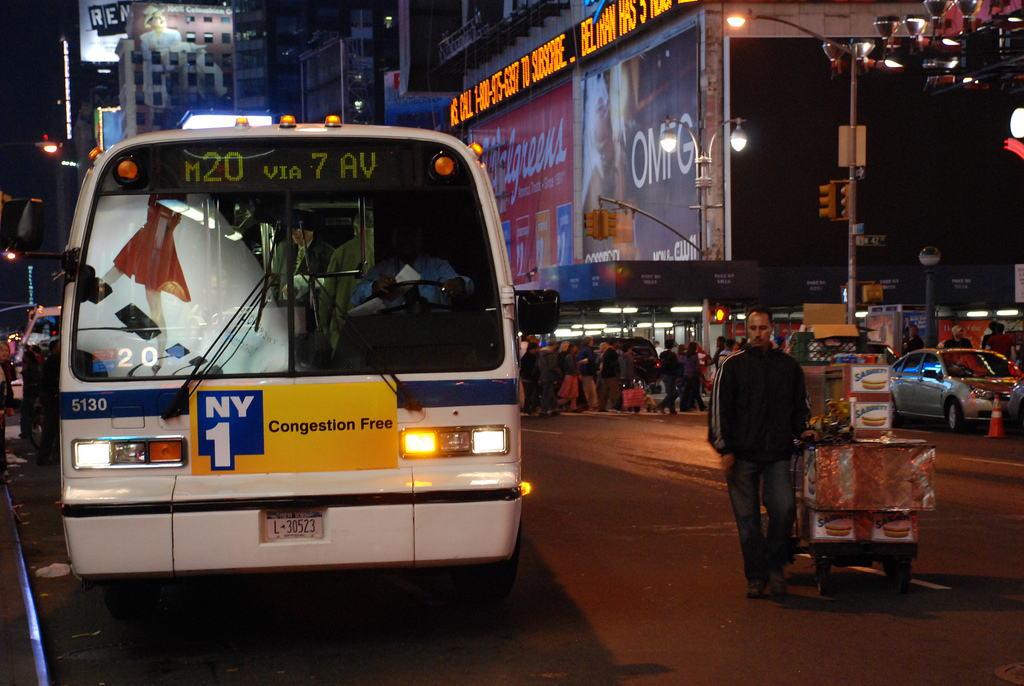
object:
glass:
[71, 138, 504, 383]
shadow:
[0, 529, 676, 684]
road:
[0, 411, 1024, 678]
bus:
[0, 115, 560, 612]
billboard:
[451, 0, 697, 286]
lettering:
[469, 77, 570, 290]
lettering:
[195, 389, 395, 470]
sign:
[189, 381, 399, 475]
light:
[726, 9, 746, 153]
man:
[707, 304, 817, 595]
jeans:
[725, 460, 794, 587]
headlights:
[71, 424, 512, 470]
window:
[840, 87, 876, 196]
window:
[792, 55, 866, 136]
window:
[726, 304, 1024, 348]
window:
[528, 300, 711, 354]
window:
[837, 44, 958, 230]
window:
[877, 137, 956, 243]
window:
[775, 50, 830, 198]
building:
[440, 0, 1023, 403]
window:
[747, 44, 826, 179]